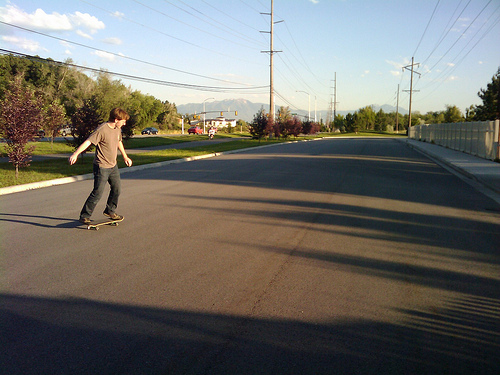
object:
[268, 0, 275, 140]
pole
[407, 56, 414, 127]
pole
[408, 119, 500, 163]
fence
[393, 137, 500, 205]
sidewalk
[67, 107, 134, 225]
man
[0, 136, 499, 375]
street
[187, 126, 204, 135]
car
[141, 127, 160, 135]
car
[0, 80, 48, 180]
tree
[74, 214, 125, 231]
skateboard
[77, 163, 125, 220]
pants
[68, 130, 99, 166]
arms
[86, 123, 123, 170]
shirt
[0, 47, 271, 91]
wires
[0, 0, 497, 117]
sky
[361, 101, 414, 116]
mountains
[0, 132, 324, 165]
sidewalk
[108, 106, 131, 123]
hair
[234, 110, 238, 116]
signals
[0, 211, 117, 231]
shadows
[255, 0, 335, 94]
power lines